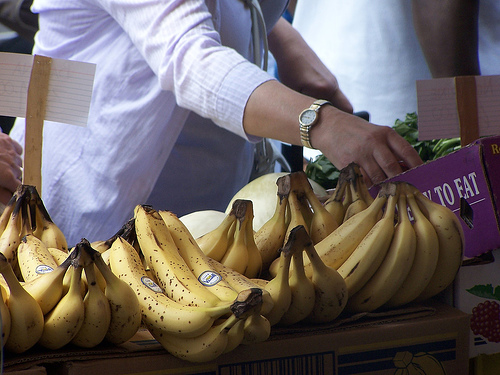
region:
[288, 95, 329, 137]
person wearing a wrist watch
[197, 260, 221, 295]
sticker on a banana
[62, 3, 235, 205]
woman wearing a white shirt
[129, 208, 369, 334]
bananas on a table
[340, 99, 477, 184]
person hand in a box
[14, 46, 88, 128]
tag on a stick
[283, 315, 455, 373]
box of bananas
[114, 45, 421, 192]
person hand in a box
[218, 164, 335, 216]
melon on a table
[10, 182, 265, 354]
bananas on a box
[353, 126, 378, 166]
part fo a hand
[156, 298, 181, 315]
part of a pwwkl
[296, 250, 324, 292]
part of a banana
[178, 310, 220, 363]
edge of a banana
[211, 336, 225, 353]
par tof a banana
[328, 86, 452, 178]
the hand of a person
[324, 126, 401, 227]
the fingers of a person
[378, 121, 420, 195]
the index of a person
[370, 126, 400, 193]
the middle finger of a person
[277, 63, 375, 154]
the wrist of a person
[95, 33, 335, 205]
the arm of a person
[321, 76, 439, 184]
the knuckles of a person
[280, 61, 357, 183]
a person wearing a watch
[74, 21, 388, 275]
a person near some bananas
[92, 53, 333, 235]
a person wearing a shirt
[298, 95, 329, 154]
gold watch on man's wrist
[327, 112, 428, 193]
the man's right hand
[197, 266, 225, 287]
sticker on the banana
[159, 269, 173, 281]
brown spotting on banana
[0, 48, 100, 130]
white sign on a stick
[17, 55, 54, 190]
wooden stick attached to sign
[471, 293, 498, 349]
berries printed on box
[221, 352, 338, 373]
barcode on the box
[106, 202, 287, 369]
bunch of yellow bananas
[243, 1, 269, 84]
tie on man's neck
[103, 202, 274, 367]
one bunch of bananas on display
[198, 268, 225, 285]
round sticker on a banana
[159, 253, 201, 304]
black spots on a banana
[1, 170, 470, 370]
lots of bunches of bananas on display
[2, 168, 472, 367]
many yellow bananas on display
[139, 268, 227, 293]
two stikcers on bananas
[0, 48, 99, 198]
brown and white sign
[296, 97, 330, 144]
gold watch on a wrist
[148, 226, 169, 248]
black mark on a banana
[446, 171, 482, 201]
white text print on a purple box